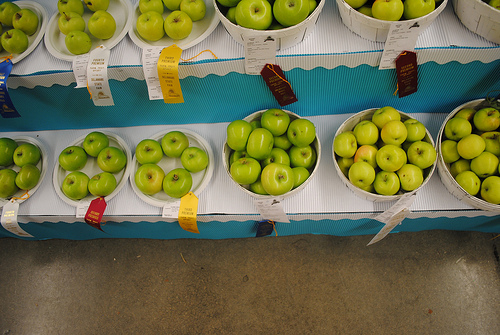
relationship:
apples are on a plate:
[7, 146, 35, 186] [10, 134, 49, 207]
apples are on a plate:
[135, 130, 206, 196] [130, 129, 213, 209]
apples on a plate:
[135, 130, 206, 196] [130, 129, 213, 209]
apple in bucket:
[379, 119, 408, 146] [326, 100, 442, 203]